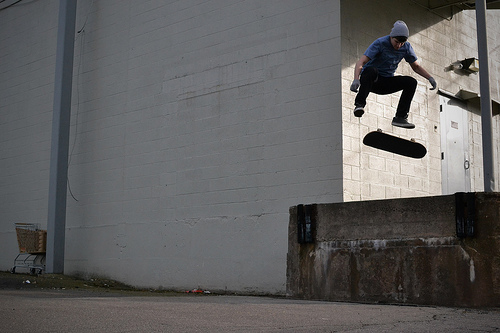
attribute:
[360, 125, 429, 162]
skateboard — black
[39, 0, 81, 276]
pole — gray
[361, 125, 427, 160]
board — upside down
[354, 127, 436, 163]
skateboard — black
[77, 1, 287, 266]
wall — brick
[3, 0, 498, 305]
wall — white, brick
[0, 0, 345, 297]
wall — brick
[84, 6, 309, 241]
wall — brick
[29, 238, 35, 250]
plastic — brown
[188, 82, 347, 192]
blocks — cement